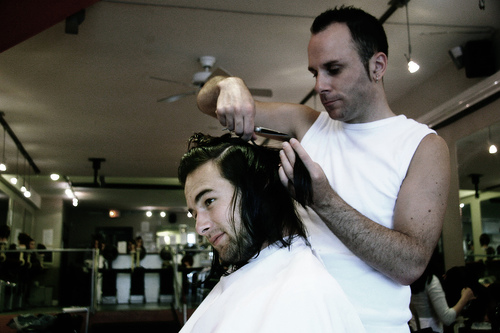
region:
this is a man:
[190, 3, 476, 331]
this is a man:
[145, 135, 367, 331]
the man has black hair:
[148, 128, 326, 258]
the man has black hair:
[247, 168, 287, 226]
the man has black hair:
[292, 156, 310, 201]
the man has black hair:
[345, 6, 395, 41]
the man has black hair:
[300, 5, 348, 34]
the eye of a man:
[199, 190, 226, 209]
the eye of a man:
[323, 56, 350, 77]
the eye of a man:
[299, 58, 324, 83]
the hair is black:
[232, 168, 263, 208]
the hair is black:
[281, 157, 321, 200]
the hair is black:
[251, 217, 279, 236]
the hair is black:
[169, 145, 207, 163]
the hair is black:
[219, 155, 259, 180]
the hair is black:
[349, 20, 386, 45]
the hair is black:
[304, 5, 332, 32]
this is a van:
[146, 50, 280, 130]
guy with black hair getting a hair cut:
[173, 122, 310, 267]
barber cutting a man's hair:
[169, 5, 459, 332]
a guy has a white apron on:
[167, 127, 332, 331]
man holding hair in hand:
[206, 84, 465, 206]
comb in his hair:
[250, 120, 303, 147]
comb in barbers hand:
[196, 61, 295, 153]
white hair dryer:
[99, 239, 142, 310]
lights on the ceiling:
[45, 167, 128, 222]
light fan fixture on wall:
[151, 53, 287, 126]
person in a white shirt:
[411, 261, 486, 331]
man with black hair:
[138, 116, 349, 331]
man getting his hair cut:
[128, 69, 330, 327]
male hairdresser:
[201, 2, 461, 332]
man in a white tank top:
[221, 10, 452, 327]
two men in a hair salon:
[163, 8, 441, 325]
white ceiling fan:
[144, 39, 272, 114]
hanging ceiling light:
[388, 1, 431, 83]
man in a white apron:
[163, 119, 342, 328]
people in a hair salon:
[105, 25, 466, 332]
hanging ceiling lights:
[3, 105, 45, 217]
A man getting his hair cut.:
[166, 117, 342, 277]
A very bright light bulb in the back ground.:
[399, 51, 424, 77]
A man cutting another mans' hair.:
[154, 2, 484, 332]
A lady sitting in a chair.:
[15, 235, 46, 275]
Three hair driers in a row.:
[94, 244, 180, 304]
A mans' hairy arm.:
[274, 138, 430, 292]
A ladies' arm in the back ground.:
[421, 273, 475, 323]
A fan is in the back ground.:
[141, 53, 272, 98]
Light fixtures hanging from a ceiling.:
[0, 108, 86, 213]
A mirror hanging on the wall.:
[449, 133, 499, 257]